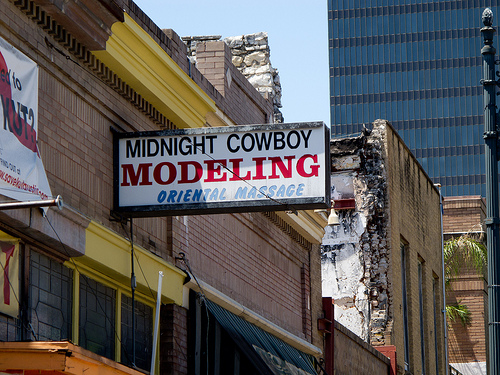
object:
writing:
[150, 180, 305, 209]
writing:
[122, 156, 377, 191]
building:
[2, 0, 329, 374]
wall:
[86, 22, 222, 172]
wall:
[66, 225, 201, 321]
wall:
[269, 183, 330, 247]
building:
[324, 121, 450, 371]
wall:
[321, 155, 408, 367]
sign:
[120, 121, 333, 220]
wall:
[6, 54, 127, 267]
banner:
[0, 39, 57, 218]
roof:
[0, 340, 147, 374]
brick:
[182, 32, 288, 113]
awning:
[201, 296, 330, 375]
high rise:
[334, 1, 488, 200]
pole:
[481, 58, 499, 363]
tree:
[438, 231, 487, 271]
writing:
[120, 125, 321, 160]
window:
[329, 69, 352, 100]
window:
[390, 75, 400, 95]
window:
[410, 63, 428, 90]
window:
[439, 64, 459, 93]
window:
[468, 88, 480, 117]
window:
[442, 94, 462, 117]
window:
[428, 92, 446, 117]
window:
[433, 150, 453, 179]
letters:
[120, 150, 321, 186]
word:
[120, 150, 321, 190]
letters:
[152, 186, 308, 203]